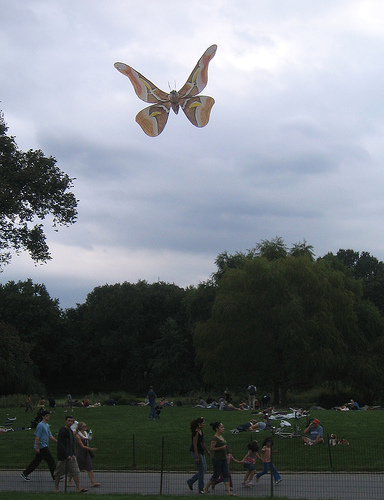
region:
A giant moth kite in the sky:
[102, 39, 272, 143]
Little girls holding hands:
[219, 432, 283, 493]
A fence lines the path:
[96, 429, 194, 498]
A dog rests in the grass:
[324, 428, 362, 451]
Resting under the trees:
[327, 395, 369, 415]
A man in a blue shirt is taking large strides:
[24, 405, 62, 484]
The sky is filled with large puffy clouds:
[79, 137, 337, 246]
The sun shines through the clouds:
[154, 5, 334, 63]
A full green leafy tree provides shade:
[178, 237, 371, 419]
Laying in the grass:
[231, 409, 282, 434]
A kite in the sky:
[113, 42, 222, 138]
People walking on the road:
[21, 410, 283, 493]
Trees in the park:
[1, 105, 378, 402]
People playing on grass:
[0, 377, 360, 449]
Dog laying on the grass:
[326, 430, 353, 449]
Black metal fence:
[0, 422, 381, 495]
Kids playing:
[227, 433, 283, 487]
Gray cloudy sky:
[1, 1, 380, 314]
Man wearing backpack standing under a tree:
[241, 378, 257, 409]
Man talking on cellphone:
[296, 413, 325, 448]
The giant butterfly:
[111, 39, 223, 142]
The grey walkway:
[1, 465, 382, 497]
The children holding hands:
[220, 436, 288, 487]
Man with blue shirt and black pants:
[20, 407, 61, 479]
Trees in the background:
[0, 114, 383, 407]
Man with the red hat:
[299, 415, 330, 450]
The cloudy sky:
[0, 0, 383, 300]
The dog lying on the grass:
[325, 433, 357, 451]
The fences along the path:
[3, 429, 381, 498]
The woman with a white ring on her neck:
[72, 417, 107, 485]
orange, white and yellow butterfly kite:
[105, 36, 238, 140]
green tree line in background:
[0, 241, 379, 387]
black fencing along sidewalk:
[6, 420, 300, 498]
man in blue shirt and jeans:
[33, 408, 56, 482]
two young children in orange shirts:
[240, 439, 284, 488]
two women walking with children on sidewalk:
[187, 408, 285, 498]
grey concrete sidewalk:
[1, 465, 380, 491]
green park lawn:
[14, 407, 376, 451]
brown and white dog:
[319, 424, 354, 453]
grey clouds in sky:
[102, 150, 322, 254]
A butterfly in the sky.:
[126, 58, 264, 134]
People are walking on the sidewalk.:
[42, 412, 314, 483]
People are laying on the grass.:
[185, 387, 327, 439]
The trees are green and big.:
[75, 272, 361, 403]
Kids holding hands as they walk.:
[227, 440, 310, 489]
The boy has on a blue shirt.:
[27, 409, 57, 471]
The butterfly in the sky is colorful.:
[116, 49, 250, 152]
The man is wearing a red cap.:
[306, 413, 327, 433]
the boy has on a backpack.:
[233, 379, 264, 403]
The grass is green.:
[99, 401, 222, 453]